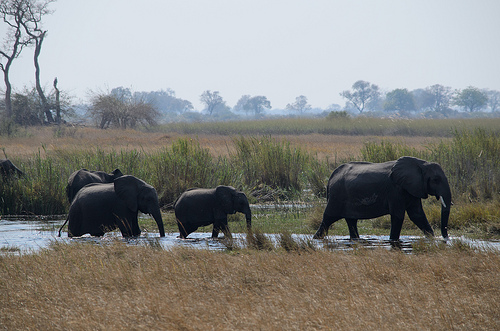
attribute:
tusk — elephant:
[433, 193, 464, 227]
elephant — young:
[172, 181, 255, 251]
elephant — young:
[54, 166, 124, 191]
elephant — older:
[313, 156, 450, 247]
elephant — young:
[58, 173, 164, 238]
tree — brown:
[338, 78, 383, 112]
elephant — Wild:
[39, 149, 482, 269]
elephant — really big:
[323, 130, 462, 252]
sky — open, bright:
[13, 7, 495, 126]